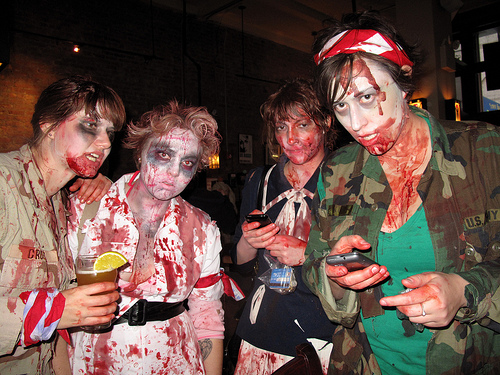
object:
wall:
[9, 68, 29, 103]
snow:
[325, 249, 378, 271]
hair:
[262, 78, 332, 155]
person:
[61, 95, 227, 373]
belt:
[107, 296, 193, 327]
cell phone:
[244, 212, 277, 249]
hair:
[322, 54, 353, 110]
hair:
[259, 82, 331, 128]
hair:
[126, 100, 219, 156]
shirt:
[424, 110, 498, 326]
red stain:
[364, 116, 435, 230]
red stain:
[270, 111, 334, 191]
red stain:
[62, 148, 103, 180]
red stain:
[230, 338, 290, 372]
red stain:
[17, 286, 71, 348]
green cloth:
[304, 138, 390, 368]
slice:
[92, 249, 129, 274]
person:
[292, 12, 499, 374]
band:
[309, 24, 411, 69]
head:
[311, 46, 413, 157]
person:
[0, 74, 127, 374]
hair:
[28, 74, 125, 144]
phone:
[323, 251, 379, 277]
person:
[226, 80, 343, 373]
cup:
[71, 251, 119, 335]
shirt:
[249, 161, 336, 349]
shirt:
[371, 207, 451, 368]